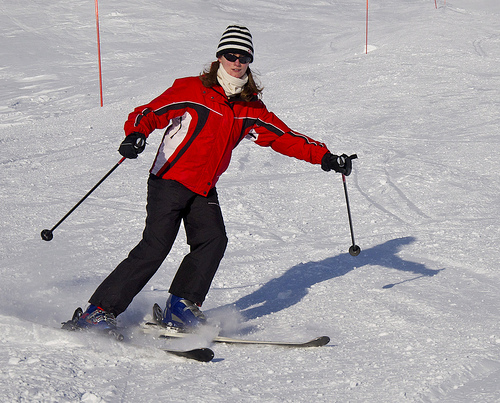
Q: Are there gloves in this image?
A: Yes, there are gloves.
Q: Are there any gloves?
A: Yes, there are gloves.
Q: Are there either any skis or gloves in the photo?
A: Yes, there are gloves.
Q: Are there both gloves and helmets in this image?
A: No, there are gloves but no helmets.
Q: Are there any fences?
A: No, there are no fences.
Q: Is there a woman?
A: Yes, there is a woman.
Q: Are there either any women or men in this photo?
A: Yes, there is a woman.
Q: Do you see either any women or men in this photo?
A: Yes, there is a woman.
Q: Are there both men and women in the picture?
A: No, there is a woman but no men.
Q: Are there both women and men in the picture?
A: No, there is a woman but no men.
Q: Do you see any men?
A: No, there are no men.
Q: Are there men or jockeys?
A: No, there are no men or jockeys.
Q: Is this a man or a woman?
A: This is a woman.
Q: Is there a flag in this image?
A: No, there are no flags.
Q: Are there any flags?
A: No, there are no flags.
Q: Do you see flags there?
A: No, there are no flags.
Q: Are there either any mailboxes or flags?
A: No, there are no flags or mailboxes.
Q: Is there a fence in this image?
A: No, there are no fences.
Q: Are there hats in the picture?
A: Yes, there is a hat.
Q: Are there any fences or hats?
A: Yes, there is a hat.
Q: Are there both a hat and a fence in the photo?
A: No, there is a hat but no fences.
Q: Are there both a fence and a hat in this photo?
A: No, there is a hat but no fences.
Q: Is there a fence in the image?
A: No, there are no fences.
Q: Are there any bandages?
A: No, there are no bandages.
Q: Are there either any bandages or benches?
A: No, there are no bandages or benches.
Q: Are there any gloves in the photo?
A: Yes, there are gloves.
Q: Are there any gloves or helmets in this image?
A: Yes, there are gloves.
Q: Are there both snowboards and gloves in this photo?
A: No, there are gloves but no snowboards.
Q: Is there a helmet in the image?
A: No, there are no helmets.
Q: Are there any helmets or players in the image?
A: No, there are no helmets or players.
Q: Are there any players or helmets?
A: No, there are no helmets or players.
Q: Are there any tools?
A: No, there are no tools.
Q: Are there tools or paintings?
A: No, there are no tools or paintings.